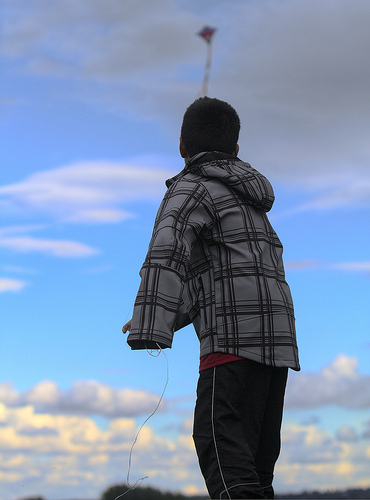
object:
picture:
[0, 0, 367, 496]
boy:
[121, 95, 300, 495]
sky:
[0, 1, 368, 500]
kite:
[193, 21, 218, 97]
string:
[116, 341, 169, 500]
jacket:
[126, 151, 302, 372]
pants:
[192, 359, 289, 498]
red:
[202, 30, 213, 36]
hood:
[188, 157, 275, 213]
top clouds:
[83, 18, 196, 83]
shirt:
[199, 352, 245, 374]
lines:
[211, 367, 232, 500]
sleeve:
[126, 182, 212, 349]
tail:
[201, 43, 213, 95]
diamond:
[194, 24, 221, 45]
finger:
[122, 319, 132, 334]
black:
[228, 378, 256, 444]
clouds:
[0, 273, 27, 298]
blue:
[1, 310, 95, 375]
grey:
[238, 281, 256, 298]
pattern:
[230, 227, 270, 340]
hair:
[180, 95, 241, 156]